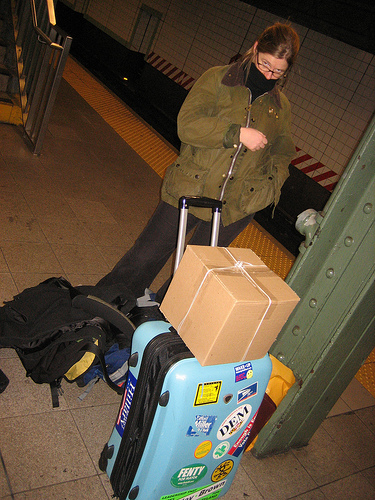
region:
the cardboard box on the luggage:
[159, 243, 300, 366]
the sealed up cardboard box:
[158, 242, 300, 366]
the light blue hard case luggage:
[98, 320, 272, 498]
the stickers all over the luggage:
[114, 361, 260, 498]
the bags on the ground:
[1, 276, 170, 409]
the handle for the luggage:
[173, 195, 223, 273]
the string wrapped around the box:
[174, 246, 271, 363]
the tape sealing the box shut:
[159, 244, 300, 367]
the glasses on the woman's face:
[255, 49, 291, 80]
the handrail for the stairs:
[8, 1, 71, 157]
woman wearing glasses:
[255, 45, 287, 75]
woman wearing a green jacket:
[158, 22, 318, 259]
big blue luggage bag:
[88, 261, 282, 496]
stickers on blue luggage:
[143, 358, 265, 497]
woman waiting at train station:
[31, 5, 362, 491]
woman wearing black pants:
[94, 167, 256, 315]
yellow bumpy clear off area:
[68, 60, 178, 183]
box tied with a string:
[157, 218, 309, 372]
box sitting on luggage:
[104, 233, 303, 499]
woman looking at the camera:
[239, 10, 303, 96]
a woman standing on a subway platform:
[35, 7, 345, 337]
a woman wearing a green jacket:
[186, 13, 309, 223]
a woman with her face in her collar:
[238, 13, 301, 106]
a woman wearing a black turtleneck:
[237, 14, 302, 114]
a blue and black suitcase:
[91, 317, 277, 499]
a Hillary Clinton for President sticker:
[114, 367, 142, 440]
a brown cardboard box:
[154, 226, 307, 369]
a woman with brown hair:
[238, 15, 300, 124]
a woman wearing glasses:
[253, 16, 301, 95]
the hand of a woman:
[235, 120, 270, 161]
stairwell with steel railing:
[0, 0, 75, 160]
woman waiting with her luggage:
[0, 18, 300, 494]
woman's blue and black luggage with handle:
[94, 315, 270, 495]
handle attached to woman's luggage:
[171, 187, 220, 315]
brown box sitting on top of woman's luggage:
[155, 241, 298, 362]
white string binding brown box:
[174, 246, 271, 363]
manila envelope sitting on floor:
[242, 347, 295, 453]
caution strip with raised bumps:
[47, 32, 373, 400]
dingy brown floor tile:
[0, 61, 374, 498]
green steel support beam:
[245, 113, 374, 460]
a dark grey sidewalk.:
[42, 169, 125, 244]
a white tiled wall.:
[181, 15, 222, 53]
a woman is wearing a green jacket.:
[195, 128, 229, 173]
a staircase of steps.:
[0, 0, 75, 156]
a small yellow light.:
[111, 63, 137, 82]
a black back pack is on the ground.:
[0, 272, 120, 407]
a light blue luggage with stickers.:
[111, 317, 270, 497]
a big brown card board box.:
[153, 240, 297, 364]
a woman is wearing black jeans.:
[142, 229, 160, 266]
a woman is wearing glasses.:
[251, 46, 294, 81]